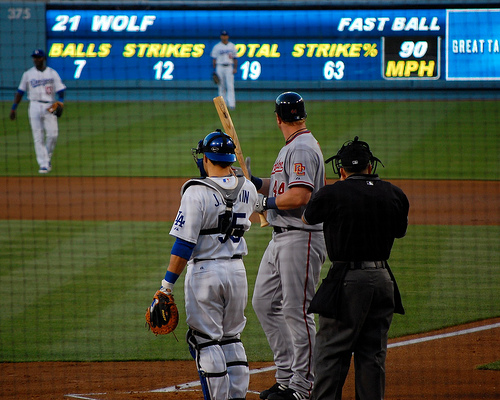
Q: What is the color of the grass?
A: Green.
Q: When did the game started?
A: Earlier.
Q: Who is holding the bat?
A: A tall man.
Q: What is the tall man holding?
A: A bat.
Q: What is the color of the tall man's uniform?
A: Gray.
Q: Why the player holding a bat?
A: To hit the ball.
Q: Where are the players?
A: In the field.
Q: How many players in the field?
A: Five.